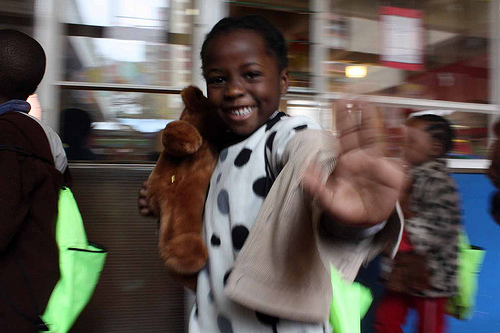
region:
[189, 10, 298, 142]
An African-American child smiling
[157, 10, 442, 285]
A small child waving and smiling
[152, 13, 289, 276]
Young girl holding teddy bear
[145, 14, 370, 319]
Child wearing polka dots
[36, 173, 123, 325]
Neon green backpack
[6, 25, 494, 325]
A group of young children wearing packpacks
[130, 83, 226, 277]
Brown teddy bear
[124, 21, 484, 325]
Children walking together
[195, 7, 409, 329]
Happy girl looking at the camera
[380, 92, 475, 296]
Child in animal print coat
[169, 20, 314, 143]
She is smiling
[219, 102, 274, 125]
Her teeth are white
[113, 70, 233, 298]
A teddy bear is being carried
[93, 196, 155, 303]
The wall is made of bricks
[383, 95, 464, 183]
The hair is braided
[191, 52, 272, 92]
Looking at the camera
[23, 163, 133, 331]
Book bag is light green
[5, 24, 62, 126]
Kid is nearly bald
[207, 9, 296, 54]
Person has short hair.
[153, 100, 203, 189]
Person holding stuffed animal.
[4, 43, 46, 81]
Person has dark hair.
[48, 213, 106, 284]
Person carrying green bag.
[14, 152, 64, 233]
Person wearing dark jacket.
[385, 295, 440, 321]
Person wearing red pants.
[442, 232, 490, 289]
Person carrying green bag.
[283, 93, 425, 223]
have is blurry from waving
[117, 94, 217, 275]
girl is carrying a teddy bear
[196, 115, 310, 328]
girl is wearing a polka dot shirt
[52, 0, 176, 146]
reflection in the window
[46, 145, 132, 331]
boy has a green bag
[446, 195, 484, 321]
girl has a green bag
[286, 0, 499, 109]
windows behind the girl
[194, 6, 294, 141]
girl is smiling at the camera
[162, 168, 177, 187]
yellow tag on the bear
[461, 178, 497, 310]
blue wall behind the girl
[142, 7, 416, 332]
young child is holding a brown teddy bear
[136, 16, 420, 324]
young child is smiling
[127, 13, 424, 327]
young child is waving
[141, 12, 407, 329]
young child is wearing a white top with black polka dots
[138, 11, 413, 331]
child is smiling and waving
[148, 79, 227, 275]
brown teddy bear in childs arms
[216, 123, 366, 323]
brown jacket held over child's arm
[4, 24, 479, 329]
child is in line with other children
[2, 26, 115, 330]
child is wearing a neon green backpack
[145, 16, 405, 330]
child has short hair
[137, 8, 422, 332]
Girl holding a stuffed brown bear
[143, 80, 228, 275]
Stuffed brown teddy bear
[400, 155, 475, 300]
Black and gray animal print coat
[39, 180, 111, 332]
Bright green tote bag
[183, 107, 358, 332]
Black and white polka dotted shirt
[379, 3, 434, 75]
Red and white sign in a window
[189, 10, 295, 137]
Girl with black hair smiling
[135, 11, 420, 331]
Girl holding hand up in a stop position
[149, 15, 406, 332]
girl waving her hand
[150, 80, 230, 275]
teddy bear the girl is holding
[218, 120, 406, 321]
light brown coat the girl is wearing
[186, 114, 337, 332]
shirt with black and gray dots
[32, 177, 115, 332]
green backpack with black zipper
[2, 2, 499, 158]
windows behind the girl